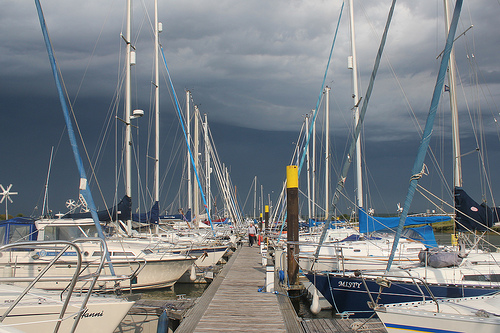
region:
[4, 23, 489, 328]
Many boats docking at the Marina.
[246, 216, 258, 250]
A boat owner walking on the bridge.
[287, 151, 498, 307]
Some boats are for fishing.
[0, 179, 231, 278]
Some boats are for cruising only.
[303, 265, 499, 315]
This blue boat is called Misty.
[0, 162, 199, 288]
Some leisure boats have satellite communications and TV.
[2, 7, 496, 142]
Blue clouds in the sky.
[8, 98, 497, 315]
These are commercial docks.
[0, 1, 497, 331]
Many boats are docked here.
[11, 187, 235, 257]
This is a leisure boat.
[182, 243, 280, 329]
long wooden pier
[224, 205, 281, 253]
person walkin on wooden pier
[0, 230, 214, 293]
beautiful white sail boat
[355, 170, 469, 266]
light blue sail on white boat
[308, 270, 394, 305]
sail boat with the letter m on it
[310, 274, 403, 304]
sail boat with the letter i on it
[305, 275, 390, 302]
sail boat with the letter s on it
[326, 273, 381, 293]
sail boat with the letter t on it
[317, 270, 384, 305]
sail boat with the letter y on it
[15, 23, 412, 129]
white and gray storm clouds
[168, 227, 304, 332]
long gray wooden pier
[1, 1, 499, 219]
gray stormy sky above pier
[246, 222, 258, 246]
person walking on the pier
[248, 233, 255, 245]
person wearing black pants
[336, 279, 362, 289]
name on blue boat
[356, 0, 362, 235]
tall white mast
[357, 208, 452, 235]
blue sail is down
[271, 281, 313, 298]
rope attached to boat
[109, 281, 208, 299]
water under boat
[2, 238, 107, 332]
silver metal hand rail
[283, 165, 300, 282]
wooden brown post with a yellow top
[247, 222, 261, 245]
person walking on a wooden pier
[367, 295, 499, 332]
white boat next to pier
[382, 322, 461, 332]
narrow blue stripe on boat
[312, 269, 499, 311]
blue boat moored next to pier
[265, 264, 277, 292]
small white post on pier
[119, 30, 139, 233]
tall white mast on boat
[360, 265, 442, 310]
metal rail on front of boat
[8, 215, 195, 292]
boat next to boat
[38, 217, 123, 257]
cabin on boat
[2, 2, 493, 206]
dark clouds in the sky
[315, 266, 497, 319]
dark blue boat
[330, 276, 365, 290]
white writing on the side of the boat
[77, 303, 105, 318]
black writing on the side of the boat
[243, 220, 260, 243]
person on the boardwalk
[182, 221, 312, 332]
light brown wooden boardwalk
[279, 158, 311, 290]
top of the post is yellow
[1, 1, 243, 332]
row of boats on the water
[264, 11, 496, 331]
boats docked at the pier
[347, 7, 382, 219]
silver pole sticking out of the boat